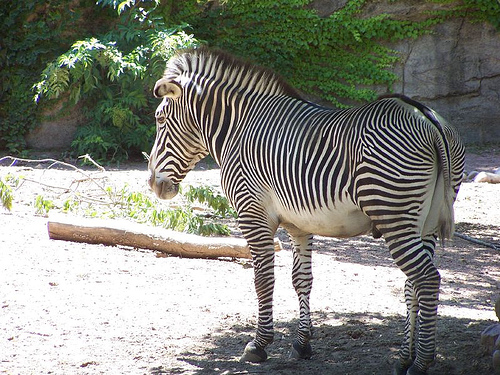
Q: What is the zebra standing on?
A: Dirt.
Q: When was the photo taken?
A: Daytime.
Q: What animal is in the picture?
A: Zebra.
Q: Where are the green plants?
A: On rock wall.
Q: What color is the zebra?
A: Black and white.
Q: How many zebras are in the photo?
A: 1.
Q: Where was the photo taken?
A: Zebra enclosure.